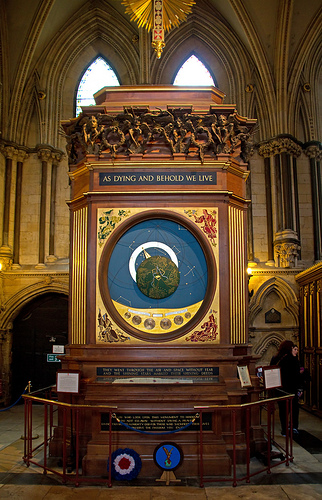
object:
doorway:
[0, 275, 82, 443]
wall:
[0, 1, 322, 382]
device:
[89, 197, 235, 349]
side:
[84, 185, 245, 363]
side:
[45, 342, 294, 494]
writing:
[96, 364, 221, 382]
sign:
[57, 368, 83, 395]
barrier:
[17, 380, 302, 487]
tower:
[23, 84, 297, 482]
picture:
[153, 440, 184, 484]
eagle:
[157, 446, 177, 470]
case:
[293, 259, 322, 431]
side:
[259, 172, 311, 462]